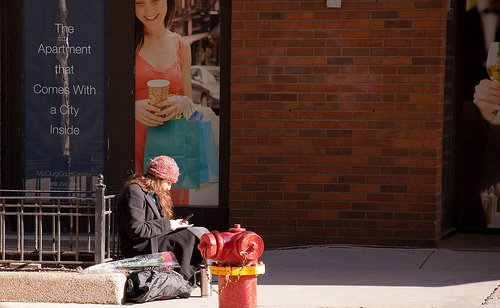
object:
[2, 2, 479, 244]
background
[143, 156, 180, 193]
head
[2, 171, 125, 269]
fence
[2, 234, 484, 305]
sidewalk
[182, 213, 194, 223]
cell phone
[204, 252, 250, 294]
chain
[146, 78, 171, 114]
coffee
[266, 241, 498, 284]
shadow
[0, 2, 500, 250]
building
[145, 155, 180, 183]
beanie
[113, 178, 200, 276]
coat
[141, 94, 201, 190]
bags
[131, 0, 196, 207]
woman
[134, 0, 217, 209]
sign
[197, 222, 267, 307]
fire hydrant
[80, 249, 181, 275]
plastic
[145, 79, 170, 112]
cup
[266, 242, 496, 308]
ground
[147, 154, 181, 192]
wearing red cap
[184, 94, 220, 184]
blue shopping bag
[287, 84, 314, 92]
brick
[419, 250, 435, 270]
crack on the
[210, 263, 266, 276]
yellow strip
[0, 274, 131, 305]
curbside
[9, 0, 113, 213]
apartment advert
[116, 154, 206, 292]
girl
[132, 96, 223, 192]
holding bags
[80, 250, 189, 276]
bouquet of roses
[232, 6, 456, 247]
brick wall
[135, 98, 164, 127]
woman's hand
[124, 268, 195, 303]
black back pack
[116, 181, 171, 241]
right arm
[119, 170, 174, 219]
brown hair